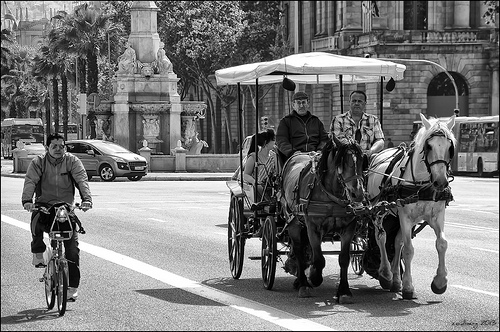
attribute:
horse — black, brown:
[278, 135, 366, 304]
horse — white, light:
[360, 114, 458, 302]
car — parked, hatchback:
[58, 137, 148, 181]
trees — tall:
[1, 1, 279, 155]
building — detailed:
[180, 1, 499, 173]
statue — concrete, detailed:
[91, 0, 206, 153]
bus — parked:
[411, 115, 499, 177]